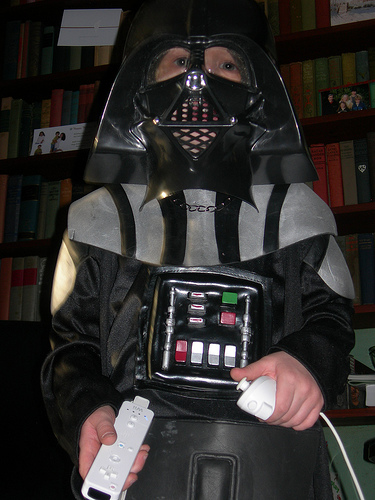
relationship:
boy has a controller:
[45, 1, 353, 498] [81, 395, 154, 499]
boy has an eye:
[45, 1, 353, 498] [222, 60, 239, 70]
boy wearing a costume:
[45, 1, 353, 498] [45, 1, 353, 498]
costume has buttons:
[45, 1, 353, 498] [222, 292, 237, 306]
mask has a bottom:
[83, 4, 320, 184] [80, 74, 320, 183]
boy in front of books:
[45, 1, 353, 498] [3, 1, 373, 313]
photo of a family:
[318, 84, 375, 115] [327, 90, 367, 109]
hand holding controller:
[80, 405, 154, 488] [81, 395, 154, 499]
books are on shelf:
[3, 1, 373, 313] [3, 5, 373, 330]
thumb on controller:
[97, 414, 119, 445] [81, 395, 154, 499]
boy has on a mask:
[45, 1, 353, 498] [83, 4, 320, 184]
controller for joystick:
[81, 395, 154, 499] [235, 375, 277, 421]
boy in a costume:
[41, 1, 356, 498] [45, 1, 353, 498]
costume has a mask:
[45, 1, 353, 498] [83, 4, 320, 184]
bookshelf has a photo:
[3, 4, 373, 499] [318, 84, 375, 115]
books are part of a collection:
[3, 1, 373, 313] [1, 1, 370, 323]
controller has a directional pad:
[81, 395, 154, 499] [107, 438, 133, 462]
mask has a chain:
[83, 4, 320, 184] [156, 114, 239, 129]